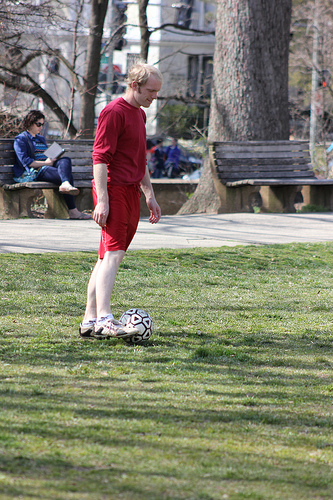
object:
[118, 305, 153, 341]
ball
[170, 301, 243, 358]
ground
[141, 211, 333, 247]
sidewalk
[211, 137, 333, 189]
bench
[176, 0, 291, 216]
tree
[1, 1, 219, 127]
building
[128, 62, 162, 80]
hair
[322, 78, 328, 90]
stop light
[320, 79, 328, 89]
light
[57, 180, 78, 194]
foot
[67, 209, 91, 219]
foot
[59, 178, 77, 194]
sandal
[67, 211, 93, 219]
sandal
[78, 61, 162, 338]
player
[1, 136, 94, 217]
bench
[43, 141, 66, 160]
book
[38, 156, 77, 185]
jeans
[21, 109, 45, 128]
hair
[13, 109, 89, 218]
woman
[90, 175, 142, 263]
shorts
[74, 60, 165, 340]
man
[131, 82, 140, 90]
man's ear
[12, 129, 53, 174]
woman's jacket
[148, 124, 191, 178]
people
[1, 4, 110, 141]
tree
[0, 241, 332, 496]
grass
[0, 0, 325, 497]
park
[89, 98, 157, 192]
man's shirt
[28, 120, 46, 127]
sunglasses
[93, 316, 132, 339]
shoe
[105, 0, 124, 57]
street light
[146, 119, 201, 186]
civilians